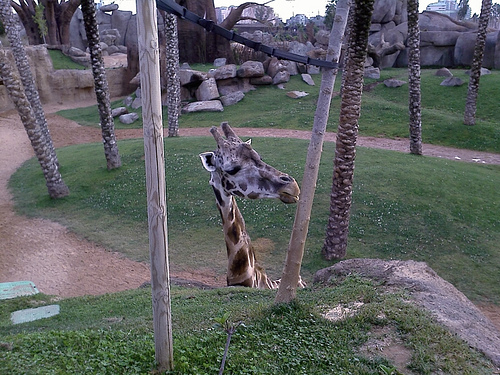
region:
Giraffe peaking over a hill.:
[184, 108, 304, 288]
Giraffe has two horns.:
[210, 110, 238, 158]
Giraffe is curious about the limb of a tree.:
[189, 104, 321, 220]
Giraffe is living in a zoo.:
[197, 72, 314, 292]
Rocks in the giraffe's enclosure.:
[173, 43, 288, 121]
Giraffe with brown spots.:
[219, 218, 256, 300]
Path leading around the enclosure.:
[30, 118, 311, 151]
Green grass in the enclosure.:
[389, 161, 482, 243]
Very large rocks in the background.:
[361, 5, 482, 63]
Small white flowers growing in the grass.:
[354, 200, 409, 235]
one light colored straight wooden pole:
[132, 1, 179, 369]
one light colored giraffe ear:
[197, 143, 216, 178]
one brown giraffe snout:
[277, 173, 299, 205]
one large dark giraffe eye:
[223, 164, 242, 179]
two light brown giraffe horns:
[210, 122, 236, 147]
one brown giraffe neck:
[213, 199, 261, 284]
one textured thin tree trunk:
[398, 1, 425, 165]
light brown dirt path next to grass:
[5, 195, 137, 287]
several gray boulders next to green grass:
[182, 56, 319, 114]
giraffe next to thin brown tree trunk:
[196, 122, 321, 301]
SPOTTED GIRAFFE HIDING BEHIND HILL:
[181, 114, 303, 294]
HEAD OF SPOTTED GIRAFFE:
[194, 116, 301, 211]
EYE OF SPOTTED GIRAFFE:
[224, 161, 247, 178]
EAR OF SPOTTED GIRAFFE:
[195, 145, 221, 176]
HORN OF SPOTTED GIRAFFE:
[216, 119, 236, 139]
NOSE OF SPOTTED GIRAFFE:
[273, 171, 298, 185]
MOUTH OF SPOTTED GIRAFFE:
[279, 188, 301, 206]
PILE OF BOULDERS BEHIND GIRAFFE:
[218, 60, 267, 97]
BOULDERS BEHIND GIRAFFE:
[108, 98, 138, 126]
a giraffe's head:
[201, 118, 305, 205]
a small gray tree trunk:
[279, 30, 334, 283]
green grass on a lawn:
[380, 157, 469, 240]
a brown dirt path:
[9, 211, 80, 278]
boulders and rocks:
[382, 7, 496, 71]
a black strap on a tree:
[161, 3, 344, 74]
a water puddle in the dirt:
[448, 155, 493, 161]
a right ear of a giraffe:
[199, 148, 217, 175]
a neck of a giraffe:
[222, 201, 255, 290]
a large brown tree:
[23, 0, 71, 43]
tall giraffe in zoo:
[185, 128, 301, 286]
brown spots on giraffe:
[229, 236, 252, 283]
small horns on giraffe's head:
[199, 124, 245, 145]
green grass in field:
[96, 160, 136, 213]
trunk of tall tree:
[339, 22, 351, 257]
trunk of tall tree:
[402, 3, 421, 164]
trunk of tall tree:
[476, 9, 481, 115]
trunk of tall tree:
[19, 19, 41, 211]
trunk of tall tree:
[79, 8, 116, 159]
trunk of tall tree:
[167, 9, 177, 136]